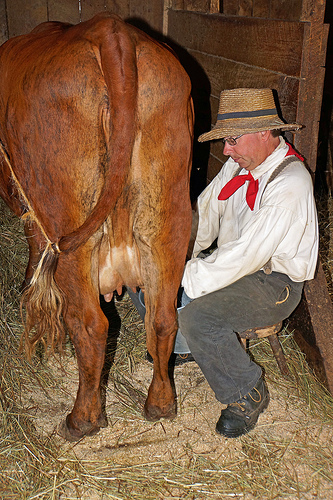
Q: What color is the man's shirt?
A: White.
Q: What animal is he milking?
A: A cow.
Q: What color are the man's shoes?
A: Black.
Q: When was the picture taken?
A: Daytime.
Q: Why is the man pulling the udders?
A: Milking the cow.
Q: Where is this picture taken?
A: A barn.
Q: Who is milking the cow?
A: A man.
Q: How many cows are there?
A: One.